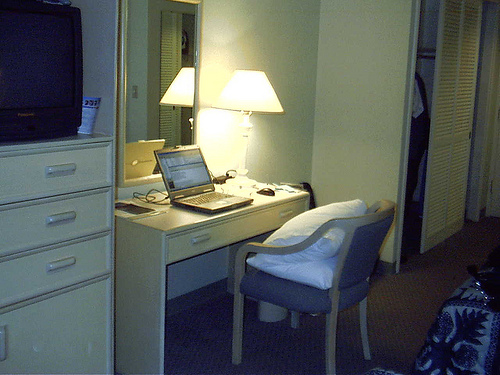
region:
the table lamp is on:
[181, 43, 281, 192]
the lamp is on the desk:
[185, 58, 281, 195]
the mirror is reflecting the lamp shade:
[96, 1, 214, 171]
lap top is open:
[140, 127, 254, 210]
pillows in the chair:
[242, 185, 417, 291]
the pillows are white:
[247, 183, 409, 275]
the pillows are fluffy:
[249, 177, 403, 279]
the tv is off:
[3, 6, 101, 138]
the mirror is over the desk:
[102, 0, 233, 187]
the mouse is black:
[252, 185, 279, 199]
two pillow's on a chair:
[225, 197, 397, 374]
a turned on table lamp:
[205, 62, 287, 202]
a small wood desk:
[117, 172, 309, 374]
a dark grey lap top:
[147, 135, 257, 215]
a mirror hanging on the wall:
[117, 1, 206, 186]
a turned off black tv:
[1, 1, 87, 143]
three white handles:
[42, 157, 81, 285]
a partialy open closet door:
[398, 3, 492, 277]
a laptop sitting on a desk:
[117, 133, 304, 371]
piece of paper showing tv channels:
[75, 87, 107, 136]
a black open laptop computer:
[150, 142, 250, 215]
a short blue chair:
[226, 197, 391, 363]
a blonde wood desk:
[113, 175, 308, 368]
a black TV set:
[0, 0, 82, 136]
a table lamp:
[205, 65, 285, 182]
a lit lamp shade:
[205, 65, 280, 110]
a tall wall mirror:
[116, 0, 197, 190]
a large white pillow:
[255, 196, 361, 259]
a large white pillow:
[242, 247, 337, 285]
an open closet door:
[418, 0, 483, 255]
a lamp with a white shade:
[212, 58, 288, 202]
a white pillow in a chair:
[251, 188, 391, 296]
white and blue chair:
[221, 170, 396, 371]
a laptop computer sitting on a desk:
[144, 138, 263, 223]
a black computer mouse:
[248, 182, 288, 206]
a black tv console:
[0, 8, 87, 153]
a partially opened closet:
[383, 1, 498, 277]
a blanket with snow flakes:
[412, 279, 494, 373]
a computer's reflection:
[118, 130, 171, 188]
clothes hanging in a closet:
[409, 50, 439, 251]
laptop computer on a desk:
[149, 133, 259, 218]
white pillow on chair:
[250, 191, 375, 258]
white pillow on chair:
[240, 251, 347, 293]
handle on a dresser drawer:
[34, 251, 79, 277]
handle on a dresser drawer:
[42, 208, 76, 227]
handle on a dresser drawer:
[40, 158, 77, 178]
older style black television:
[0, 4, 95, 145]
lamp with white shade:
[200, 60, 296, 178]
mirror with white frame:
[112, 2, 212, 192]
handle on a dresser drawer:
[190, 228, 217, 247]